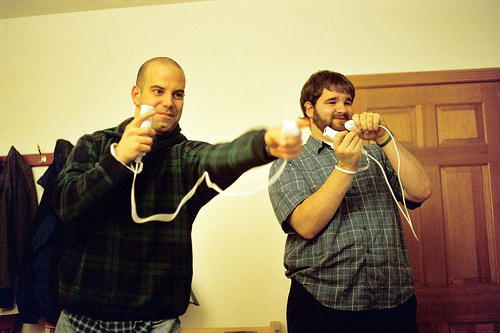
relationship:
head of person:
[294, 67, 360, 140] [262, 68, 437, 331]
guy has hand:
[266, 68, 432, 332] [331, 124, 371, 168]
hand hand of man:
[331, 129, 362, 175] [274, 99, 395, 282]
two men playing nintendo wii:
[49, 57, 434, 333] [299, 99, 380, 233]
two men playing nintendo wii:
[74, 69, 410, 223] [331, 115, 371, 196]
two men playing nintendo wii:
[49, 57, 434, 333] [124, 129, 385, 198]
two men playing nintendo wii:
[49, 57, 434, 333] [104, 117, 384, 203]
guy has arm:
[266, 68, 432, 332] [182, 118, 305, 207]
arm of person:
[58, 112, 155, 237] [53, 56, 300, 330]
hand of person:
[331, 129, 362, 175] [53, 56, 300, 330]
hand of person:
[264, 124, 303, 160] [53, 56, 300, 330]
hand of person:
[331, 129, 362, 175] [262, 68, 437, 331]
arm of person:
[268, 159, 356, 239] [262, 68, 437, 331]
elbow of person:
[407, 179, 434, 203] [262, 68, 437, 331]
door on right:
[344, 68, 496, 329] [240, 5, 497, 330]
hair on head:
[298, 69, 357, 120] [129, 56, 187, 131]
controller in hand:
[321, 123, 369, 166] [261, 119, 302, 159]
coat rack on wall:
[0, 153, 56, 169] [2, 3, 496, 330]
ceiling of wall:
[0, 0, 216, 19] [2, 3, 496, 330]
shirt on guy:
[61, 116, 279, 324] [266, 68, 432, 332]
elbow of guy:
[289, 214, 332, 240] [266, 68, 432, 332]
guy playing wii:
[266, 68, 432, 332] [131, 106, 301, 225]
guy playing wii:
[266, 68, 432, 332] [325, 123, 419, 241]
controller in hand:
[322, 123, 367, 154] [330, 131, 366, 171]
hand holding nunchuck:
[331, 129, 362, 175] [344, 115, 358, 134]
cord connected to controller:
[361, 124, 420, 240] [315, 125, 367, 156]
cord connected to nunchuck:
[361, 124, 420, 240] [345, 118, 356, 130]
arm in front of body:
[189, 124, 271, 193] [47, 57, 307, 331]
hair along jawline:
[298, 69, 357, 120] [308, 118, 328, 133]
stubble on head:
[132, 54, 186, 87] [129, 56, 187, 131]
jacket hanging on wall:
[30, 136, 77, 326] [2, 3, 496, 330]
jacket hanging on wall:
[0, 146, 40, 313] [2, 3, 496, 330]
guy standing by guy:
[266, 68, 432, 332] [266, 68, 432, 332]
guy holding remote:
[266, 68, 432, 332] [321, 124, 366, 155]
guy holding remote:
[266, 68, 432, 332] [132, 102, 153, 162]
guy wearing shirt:
[266, 68, 432, 332] [268, 126, 417, 316]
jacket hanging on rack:
[30, 136, 77, 326] [0, 149, 53, 168]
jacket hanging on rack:
[0, 146, 40, 313] [0, 149, 53, 168]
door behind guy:
[344, 68, 496, 329] [266, 68, 432, 332]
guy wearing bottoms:
[266, 68, 432, 332] [285, 279, 421, 331]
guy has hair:
[266, 68, 432, 332] [298, 71, 356, 121]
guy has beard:
[266, 68, 432, 332] [311, 103, 345, 134]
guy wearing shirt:
[263, 68, 430, 330] [269, 136, 421, 307]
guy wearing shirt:
[266, 68, 432, 332] [61, 116, 279, 324]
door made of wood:
[344, 68, 496, 329] [439, 88, 496, 316]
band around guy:
[376, 131, 395, 149] [266, 68, 432, 332]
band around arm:
[376, 131, 395, 149] [373, 131, 435, 203]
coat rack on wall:
[2, 153, 55, 168] [5, 8, 122, 118]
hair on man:
[308, 103, 340, 132] [248, 61, 427, 324]